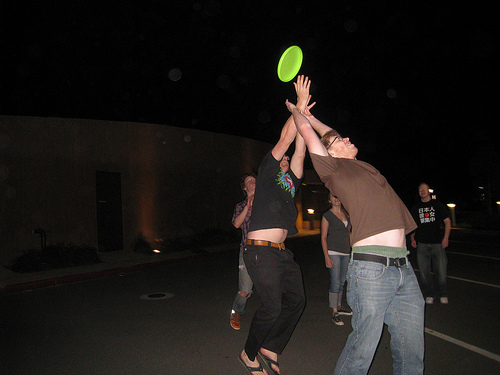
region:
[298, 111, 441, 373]
Man wearing a brown shirt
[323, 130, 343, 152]
Glasses on man's face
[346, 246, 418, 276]
Belt around man's waist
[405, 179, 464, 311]
Man wearing a black shirt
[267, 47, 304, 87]
Frisbee in the air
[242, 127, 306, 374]
Man wearing black pants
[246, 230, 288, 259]
Belt around man's waist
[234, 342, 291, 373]
Man wearing flip flops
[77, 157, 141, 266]
Door on the building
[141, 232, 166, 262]
Light on the sidewalk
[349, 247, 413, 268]
A black leather belt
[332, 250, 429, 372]
A pair of blue jeans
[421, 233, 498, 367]
White lines on the ground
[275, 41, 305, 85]
A round green frisbee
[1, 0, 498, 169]
The sky is very dark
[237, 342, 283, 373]
A pair of flip flops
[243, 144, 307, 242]
A shirt is black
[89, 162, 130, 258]
A door on a building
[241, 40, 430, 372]
Two people playing frisbee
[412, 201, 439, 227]
White writing on a black shirt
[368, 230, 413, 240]
man's white bare belly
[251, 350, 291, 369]
man wearing flip flops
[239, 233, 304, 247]
brown belt around man's waist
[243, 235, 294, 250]
black loops in pants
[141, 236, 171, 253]
light shining on the ground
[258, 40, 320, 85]
green frisbee in the air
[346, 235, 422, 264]
edge of green underwear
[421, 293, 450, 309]
white sneakers on feet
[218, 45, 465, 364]
men playing with frisbee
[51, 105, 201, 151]
flat roof on house top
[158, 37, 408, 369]
guys playing frisbee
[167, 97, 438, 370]
men playing frisbee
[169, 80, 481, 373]
men playing frisbee at night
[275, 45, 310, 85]
yellow frisbee in the air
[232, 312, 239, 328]
red shoe on foot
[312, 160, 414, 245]
brown t-shirt on man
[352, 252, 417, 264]
black belt on jean pants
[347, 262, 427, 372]
blue jeans on legs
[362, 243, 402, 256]
green boxers on man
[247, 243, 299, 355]
black pants on man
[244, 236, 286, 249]
the brown belt of a person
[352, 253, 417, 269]
the brown belt of a person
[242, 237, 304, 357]
a pair of jeans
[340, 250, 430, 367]
a pair of jeans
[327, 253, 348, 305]
a pair of light blue folded jeans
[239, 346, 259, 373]
a brown and black flip flop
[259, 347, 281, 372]
a brown and black flip flop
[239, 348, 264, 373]
a bare white foot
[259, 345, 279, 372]
a bare white foot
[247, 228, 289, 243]
the belly of a person jumping